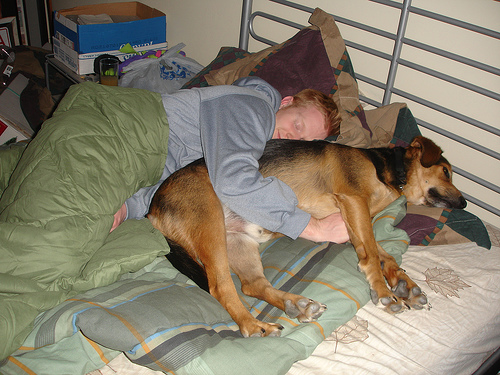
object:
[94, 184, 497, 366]
comforter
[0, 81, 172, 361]
blanket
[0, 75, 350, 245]
guy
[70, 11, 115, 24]
staff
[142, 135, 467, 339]
dog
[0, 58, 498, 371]
bed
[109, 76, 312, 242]
hoodie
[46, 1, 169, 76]
box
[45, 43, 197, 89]
table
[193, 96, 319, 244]
arm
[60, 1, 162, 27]
stuff